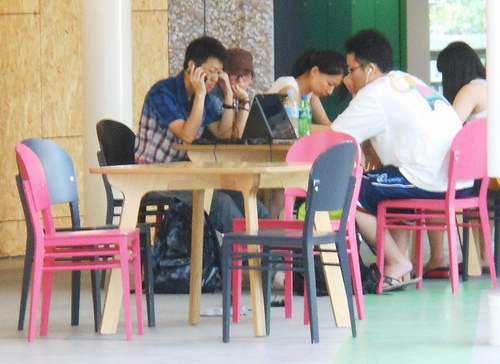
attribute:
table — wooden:
[92, 159, 359, 191]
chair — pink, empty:
[232, 130, 368, 325]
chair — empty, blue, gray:
[219, 141, 361, 346]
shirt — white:
[328, 69, 477, 196]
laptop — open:
[256, 97, 305, 144]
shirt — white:
[463, 75, 500, 180]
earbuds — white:
[365, 68, 373, 85]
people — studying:
[132, 34, 499, 294]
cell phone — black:
[184, 58, 208, 85]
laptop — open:
[202, 93, 287, 143]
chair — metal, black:
[94, 120, 178, 290]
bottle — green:
[298, 95, 313, 137]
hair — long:
[294, 47, 348, 79]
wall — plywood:
[0, 1, 168, 263]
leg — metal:
[99, 208, 114, 291]